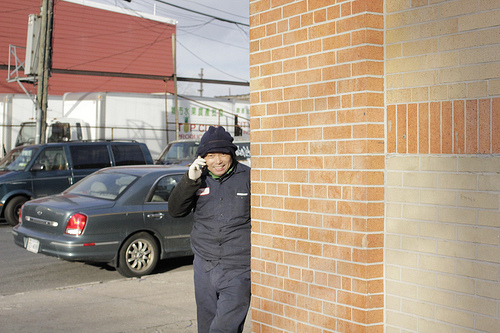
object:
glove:
[187, 159, 206, 184]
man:
[165, 121, 251, 332]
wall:
[53, 88, 195, 138]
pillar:
[248, 0, 385, 332]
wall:
[386, 2, 498, 331]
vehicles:
[0, 140, 253, 270]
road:
[2, 214, 132, 308]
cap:
[195, 121, 236, 154]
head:
[197, 134, 239, 177]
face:
[201, 154, 239, 175]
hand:
[183, 156, 209, 180]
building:
[248, 0, 498, 330]